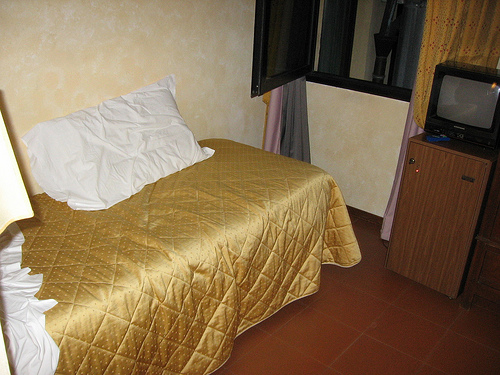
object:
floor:
[200, 206, 499, 374]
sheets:
[0, 224, 63, 375]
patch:
[242, 276, 249, 285]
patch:
[263, 294, 272, 302]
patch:
[125, 288, 133, 296]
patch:
[243, 160, 251, 165]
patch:
[304, 240, 312, 248]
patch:
[121, 228, 127, 235]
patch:
[123, 281, 134, 289]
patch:
[128, 255, 137, 264]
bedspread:
[16, 137, 363, 374]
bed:
[0, 138, 363, 374]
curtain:
[280, 76, 312, 164]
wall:
[0, 0, 267, 197]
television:
[421, 59, 499, 154]